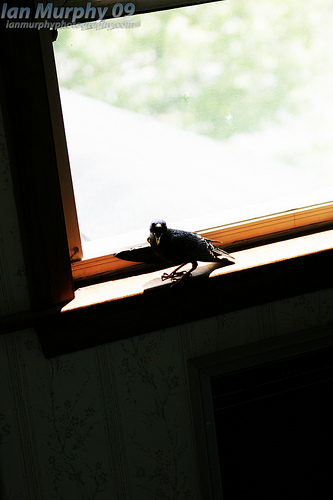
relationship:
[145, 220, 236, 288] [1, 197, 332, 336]
bird on sill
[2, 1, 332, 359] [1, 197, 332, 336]
window has sill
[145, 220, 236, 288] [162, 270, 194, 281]
bird has foot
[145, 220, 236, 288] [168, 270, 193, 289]
bird has foot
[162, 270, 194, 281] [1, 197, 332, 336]
foot on sill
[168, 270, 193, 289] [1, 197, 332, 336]
foot on sill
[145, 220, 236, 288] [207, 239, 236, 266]
bird has tail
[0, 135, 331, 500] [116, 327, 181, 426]
wallpaper has flower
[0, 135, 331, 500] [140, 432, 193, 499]
wallpaper has flower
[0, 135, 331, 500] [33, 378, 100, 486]
wallpaper has flower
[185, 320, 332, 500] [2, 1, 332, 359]
vent under window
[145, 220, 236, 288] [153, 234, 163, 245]
bird has beak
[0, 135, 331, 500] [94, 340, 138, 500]
wallpaper has line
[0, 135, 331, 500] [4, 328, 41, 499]
wallpaper has line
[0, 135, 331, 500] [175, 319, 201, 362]
wallpaper has line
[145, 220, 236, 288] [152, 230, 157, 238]
bird has eye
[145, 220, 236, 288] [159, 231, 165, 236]
bird has eye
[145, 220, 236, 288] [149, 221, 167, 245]
bird has head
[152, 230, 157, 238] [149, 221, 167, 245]
eye on head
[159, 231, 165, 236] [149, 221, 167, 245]
eye on head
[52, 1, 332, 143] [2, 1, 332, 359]
vegetation outside window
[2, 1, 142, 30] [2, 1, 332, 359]
wording above window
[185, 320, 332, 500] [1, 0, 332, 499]
vent on wall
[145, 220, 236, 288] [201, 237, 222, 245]
bird has wing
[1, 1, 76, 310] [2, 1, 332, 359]
frame on side of window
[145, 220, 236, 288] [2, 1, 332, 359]
bird in front of window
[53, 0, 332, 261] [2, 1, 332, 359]
view outside window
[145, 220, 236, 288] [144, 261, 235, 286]
bird has shadow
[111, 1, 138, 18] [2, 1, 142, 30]
09 in wording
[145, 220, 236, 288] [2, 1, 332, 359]
bird inside window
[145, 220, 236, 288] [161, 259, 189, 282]
bird has leg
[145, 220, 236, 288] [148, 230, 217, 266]
bird has body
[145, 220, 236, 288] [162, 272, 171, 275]
bird has talon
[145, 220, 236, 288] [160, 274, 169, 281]
bird has talon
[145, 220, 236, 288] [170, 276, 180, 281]
bird has talon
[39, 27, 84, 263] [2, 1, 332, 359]
frame on window